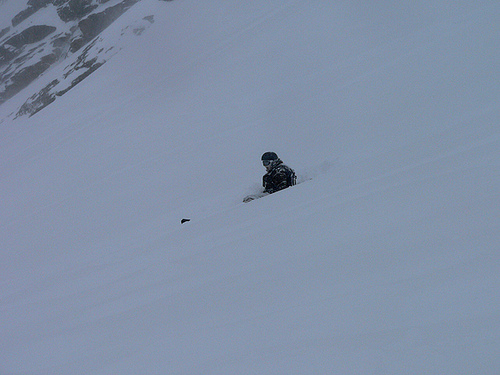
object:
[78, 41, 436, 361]
slope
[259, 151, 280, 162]
hat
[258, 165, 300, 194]
jacket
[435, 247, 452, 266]
part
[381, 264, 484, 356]
surface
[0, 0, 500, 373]
mountain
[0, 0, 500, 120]
mountain top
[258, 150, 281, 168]
head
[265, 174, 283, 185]
black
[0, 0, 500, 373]
snow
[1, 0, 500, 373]
ground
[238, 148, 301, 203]
man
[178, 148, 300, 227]
man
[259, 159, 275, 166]
goggles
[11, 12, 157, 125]
rock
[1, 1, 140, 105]
rock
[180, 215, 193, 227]
foot